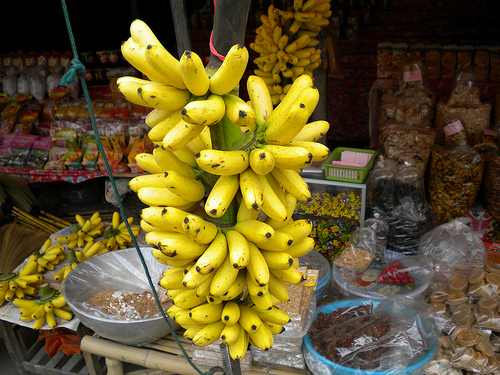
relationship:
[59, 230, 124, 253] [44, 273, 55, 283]
bananas on platform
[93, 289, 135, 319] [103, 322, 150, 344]
spices in a bowl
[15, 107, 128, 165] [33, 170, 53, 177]
snacks on a stand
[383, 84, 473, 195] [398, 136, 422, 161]
bags of banana peels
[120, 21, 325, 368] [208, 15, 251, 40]
bananas hanging on a stick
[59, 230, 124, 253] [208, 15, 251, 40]
bananas hanged on a stick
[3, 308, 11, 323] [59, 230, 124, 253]
table has bananas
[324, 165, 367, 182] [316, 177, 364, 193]
basket sitting on shelf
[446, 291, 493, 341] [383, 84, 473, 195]
cookies in bags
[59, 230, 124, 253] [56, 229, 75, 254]
bananas on display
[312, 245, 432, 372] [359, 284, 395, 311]
bowls in plastic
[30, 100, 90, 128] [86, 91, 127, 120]
packet of cerals